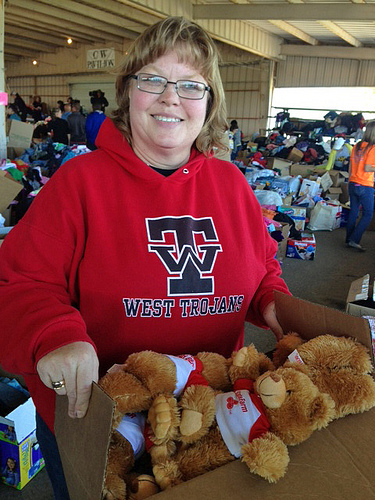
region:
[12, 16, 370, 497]
A woman holding a box of teddy bears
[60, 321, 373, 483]
A box of teddy bears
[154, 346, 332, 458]
Teddy bears with red and white shirts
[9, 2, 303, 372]
A woman wearing a red sweatshirt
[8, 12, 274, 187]
A woman wearing glasses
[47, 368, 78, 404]
A woman wearing a ring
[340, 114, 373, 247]
A girl wearing an orange shirt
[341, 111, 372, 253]
A girl wearing blue jeans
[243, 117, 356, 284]
Bags and boxes of stuff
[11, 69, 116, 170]
People in the background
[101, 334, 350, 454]
Teddy bears in a box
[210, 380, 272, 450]
The bears are wearing State Farm shirts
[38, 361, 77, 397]
The woman has a ring on her right hand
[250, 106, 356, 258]
Tons of boxes and bags full of stuff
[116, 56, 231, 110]
The woman is wearing glasses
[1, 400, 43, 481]
An empty toy box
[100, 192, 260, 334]
West Trojans sweatshirt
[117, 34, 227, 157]
The woman is smiling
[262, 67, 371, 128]
The door is open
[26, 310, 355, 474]
The woman is holding the box of bears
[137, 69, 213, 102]
Glasses on a lady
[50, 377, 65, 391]
Ring on her finger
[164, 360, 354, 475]
Bear with tshirt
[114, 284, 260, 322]
West Trojans sweatshirt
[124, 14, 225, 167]
Lady with blond hair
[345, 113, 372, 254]
Lady with orange shirt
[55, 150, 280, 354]
Red West Trojans sweatshirt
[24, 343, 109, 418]
Lady's hand with ring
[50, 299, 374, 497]
Box of bears with State Farm shirts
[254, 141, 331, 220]
Boxes of clothes and toys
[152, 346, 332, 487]
a brown plush teddy bear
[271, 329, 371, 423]
a brown plush teddy bear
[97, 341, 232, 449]
a brown plush teddy bear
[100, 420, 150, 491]
a brown plush teddy bear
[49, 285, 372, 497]
a cardboard box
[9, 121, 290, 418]
a red college sweat shirt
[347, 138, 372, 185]
a neon orange t-shirt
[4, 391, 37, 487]
a yellow and blue cardboard box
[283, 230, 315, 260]
a large cardboard box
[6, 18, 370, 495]
a woman holding a box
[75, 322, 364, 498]
bunch of brown teddy bears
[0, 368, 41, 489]
empty box on counter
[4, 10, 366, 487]
woman holding a box of teddy bears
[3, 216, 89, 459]
woman wearing a gold ring on left hand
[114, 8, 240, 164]
woman wearing glasses and smiling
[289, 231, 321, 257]
red and blue box on floor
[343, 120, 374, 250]
person wearing an orange top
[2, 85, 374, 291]
lots of toys and gifts on floor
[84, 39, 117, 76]
white and black sign hanging on wall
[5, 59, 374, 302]
many people looking at packages on floor